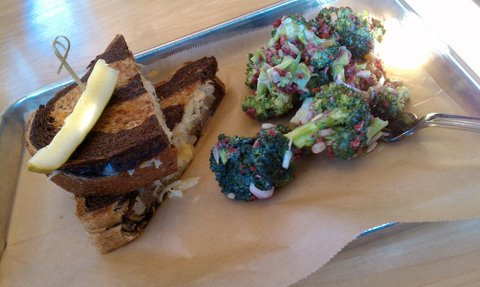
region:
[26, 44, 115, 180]
a small piece of pickle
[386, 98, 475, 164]
a metal fork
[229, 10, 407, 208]
broccoli and onions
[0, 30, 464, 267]
a white piece of wax paper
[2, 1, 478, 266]
a silver metal tray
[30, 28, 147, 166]
a piece of multi colored bread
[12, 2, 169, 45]
reflection of light on the table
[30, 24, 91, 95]
a tooth pick sticking in the bread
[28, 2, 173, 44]
a tan wooden table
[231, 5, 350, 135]
red peppers on the broccoli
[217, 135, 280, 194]
this is a broccoli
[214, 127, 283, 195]
the broccoli is green in color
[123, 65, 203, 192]
this is a cake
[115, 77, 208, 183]
the cake is brown in color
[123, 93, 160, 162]
the cake is sliced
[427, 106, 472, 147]
this is a spoon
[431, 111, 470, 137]
the spoon is shiny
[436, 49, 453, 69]
this is a tray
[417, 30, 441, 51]
the tray is silvery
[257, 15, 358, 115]
the broccoli is creamy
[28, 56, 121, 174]
pale green pickle slice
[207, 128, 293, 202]
chopped green broccoli floret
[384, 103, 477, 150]
stainless steel utensil handle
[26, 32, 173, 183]
sandwich on marble rye bread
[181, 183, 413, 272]
brown wax paper liner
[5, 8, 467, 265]
silver metal food tray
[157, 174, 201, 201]
small piece of sauerkraut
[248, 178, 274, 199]
chopped red onion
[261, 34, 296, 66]
bits of bacon crumbles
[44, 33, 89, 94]
toothpick holding sandwich together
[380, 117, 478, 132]
this is a spoon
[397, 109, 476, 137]
the spoon is metallic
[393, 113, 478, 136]
the spoon is shiny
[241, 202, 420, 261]
this is a paper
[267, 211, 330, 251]
the paper is brown in color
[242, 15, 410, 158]
this is some ice cream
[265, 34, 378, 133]
the ice cream has several colors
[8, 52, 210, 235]
these are pieces of cake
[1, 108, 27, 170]
this is a tray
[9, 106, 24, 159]
the tray is metallic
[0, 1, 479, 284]
a cafeteria tray on the table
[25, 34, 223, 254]
a sandwich on the tray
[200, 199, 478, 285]
parchment paper on top of the tray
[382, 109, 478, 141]
a plastic spoon on the tray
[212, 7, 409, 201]
a vegetable salad on the tray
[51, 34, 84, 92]
a plastic spear toothpick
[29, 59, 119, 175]
a pickle slice on top of the sandwich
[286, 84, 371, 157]
a broccoli head in the salad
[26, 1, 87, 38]
a reflection of the light on the wooden table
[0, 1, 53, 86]
a wooden lunch table